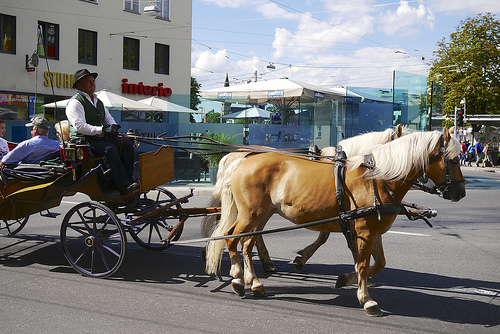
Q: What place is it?
A: It is a parking lot.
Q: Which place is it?
A: It is a parking lot.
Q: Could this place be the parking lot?
A: Yes, it is the parking lot.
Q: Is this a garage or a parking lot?
A: It is a parking lot.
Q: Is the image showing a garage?
A: No, the picture is showing a parking lot.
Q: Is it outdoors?
A: Yes, it is outdoors.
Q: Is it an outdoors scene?
A: Yes, it is outdoors.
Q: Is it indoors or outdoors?
A: It is outdoors.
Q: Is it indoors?
A: No, it is outdoors.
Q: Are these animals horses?
A: Yes, all the animals are horses.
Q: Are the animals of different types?
A: No, all the animals are horses.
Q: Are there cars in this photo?
A: No, there are no cars.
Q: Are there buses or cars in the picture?
A: No, there are no cars or buses.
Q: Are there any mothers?
A: No, there are no mothers.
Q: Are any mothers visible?
A: No, there are no mothers.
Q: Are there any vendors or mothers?
A: No, there are no mothers or vendors.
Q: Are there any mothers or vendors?
A: No, there are no mothers or vendors.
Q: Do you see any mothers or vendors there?
A: No, there are no mothers or vendors.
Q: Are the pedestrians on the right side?
A: Yes, the pedestrians are on the right of the image.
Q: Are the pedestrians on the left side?
A: No, the pedestrians are on the right of the image.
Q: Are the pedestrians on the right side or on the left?
A: The pedestrians are on the right of the image.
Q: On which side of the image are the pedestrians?
A: The pedestrians are on the right of the image.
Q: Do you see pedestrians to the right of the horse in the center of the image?
A: Yes, there are pedestrians to the right of the horse.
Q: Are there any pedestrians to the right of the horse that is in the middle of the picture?
A: Yes, there are pedestrians to the right of the horse.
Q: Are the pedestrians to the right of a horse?
A: Yes, the pedestrians are to the right of a horse.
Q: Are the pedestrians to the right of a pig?
A: No, the pedestrians are to the right of a horse.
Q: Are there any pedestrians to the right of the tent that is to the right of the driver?
A: Yes, there are pedestrians to the right of the tent.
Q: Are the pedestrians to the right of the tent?
A: Yes, the pedestrians are to the right of the tent.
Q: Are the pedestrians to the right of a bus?
A: No, the pedestrians are to the right of the tent.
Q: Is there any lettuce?
A: Yes, there is lettuce.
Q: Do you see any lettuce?
A: Yes, there is lettuce.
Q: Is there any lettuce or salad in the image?
A: Yes, there is lettuce.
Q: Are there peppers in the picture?
A: No, there are no peppers.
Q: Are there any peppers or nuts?
A: No, there are no peppers or nuts.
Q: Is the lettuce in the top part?
A: Yes, the lettuce is in the top of the image.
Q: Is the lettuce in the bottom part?
A: No, the lettuce is in the top of the image.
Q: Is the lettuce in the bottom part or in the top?
A: The lettuce is in the top of the image.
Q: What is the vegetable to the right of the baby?
A: The vegetable is lettuce.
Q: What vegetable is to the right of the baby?
A: The vegetable is lettuce.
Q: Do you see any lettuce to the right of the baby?
A: Yes, there is lettuce to the right of the baby.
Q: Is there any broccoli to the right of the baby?
A: No, there is lettuce to the right of the baby.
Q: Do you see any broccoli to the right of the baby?
A: No, there is lettuce to the right of the baby.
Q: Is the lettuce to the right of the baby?
A: Yes, the lettuce is to the right of the baby.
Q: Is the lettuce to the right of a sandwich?
A: No, the lettuce is to the right of the baby.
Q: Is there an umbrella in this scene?
A: Yes, there is an umbrella.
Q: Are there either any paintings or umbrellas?
A: Yes, there is an umbrella.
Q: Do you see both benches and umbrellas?
A: No, there is an umbrella but no benches.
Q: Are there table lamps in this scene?
A: No, there are no table lamps.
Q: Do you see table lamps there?
A: No, there are no table lamps.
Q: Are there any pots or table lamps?
A: No, there are no table lamps or pots.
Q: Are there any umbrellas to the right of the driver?
A: Yes, there is an umbrella to the right of the driver.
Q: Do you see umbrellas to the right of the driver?
A: Yes, there is an umbrella to the right of the driver.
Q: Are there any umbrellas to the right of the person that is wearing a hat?
A: Yes, there is an umbrella to the right of the driver.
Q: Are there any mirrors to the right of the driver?
A: No, there is an umbrella to the right of the driver.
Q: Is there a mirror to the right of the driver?
A: No, there is an umbrella to the right of the driver.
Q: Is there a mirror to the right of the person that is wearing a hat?
A: No, there is an umbrella to the right of the driver.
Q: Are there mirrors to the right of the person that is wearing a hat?
A: No, there is an umbrella to the right of the driver.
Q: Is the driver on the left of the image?
A: Yes, the driver is on the left of the image.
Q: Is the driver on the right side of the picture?
A: No, the driver is on the left of the image.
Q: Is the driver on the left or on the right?
A: The driver is on the left of the image.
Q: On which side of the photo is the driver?
A: The driver is on the left of the image.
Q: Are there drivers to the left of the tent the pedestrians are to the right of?
A: Yes, there is a driver to the left of the tent.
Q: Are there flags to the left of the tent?
A: No, there is a driver to the left of the tent.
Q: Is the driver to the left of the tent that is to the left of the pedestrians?
A: Yes, the driver is to the left of the tent.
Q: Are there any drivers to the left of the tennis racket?
A: Yes, there is a driver to the left of the tennis racket.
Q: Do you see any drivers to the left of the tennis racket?
A: Yes, there is a driver to the left of the tennis racket.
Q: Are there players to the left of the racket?
A: No, there is a driver to the left of the racket.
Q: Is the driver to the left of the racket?
A: Yes, the driver is to the left of the racket.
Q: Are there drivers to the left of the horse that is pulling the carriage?
A: Yes, there is a driver to the left of the horse.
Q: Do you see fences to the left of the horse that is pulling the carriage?
A: No, there is a driver to the left of the horse.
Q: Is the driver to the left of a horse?
A: Yes, the driver is to the left of a horse.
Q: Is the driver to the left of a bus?
A: No, the driver is to the left of a horse.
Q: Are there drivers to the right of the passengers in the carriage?
A: Yes, there is a driver to the right of the passengers.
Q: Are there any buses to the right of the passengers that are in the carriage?
A: No, there is a driver to the right of the passengers.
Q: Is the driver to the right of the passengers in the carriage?
A: Yes, the driver is to the right of the passengers.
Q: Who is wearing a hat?
A: The driver is wearing a hat.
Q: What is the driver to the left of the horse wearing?
A: The driver is wearing a hat.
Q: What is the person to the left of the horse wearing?
A: The driver is wearing a hat.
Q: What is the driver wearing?
A: The driver is wearing a hat.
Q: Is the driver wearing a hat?
A: Yes, the driver is wearing a hat.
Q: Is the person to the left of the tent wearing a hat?
A: Yes, the driver is wearing a hat.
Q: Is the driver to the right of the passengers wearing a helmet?
A: No, the driver is wearing a hat.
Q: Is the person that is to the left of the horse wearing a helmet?
A: No, the driver is wearing a hat.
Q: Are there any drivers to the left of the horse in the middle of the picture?
A: Yes, there is a driver to the left of the horse.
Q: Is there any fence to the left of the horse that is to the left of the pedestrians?
A: No, there is a driver to the left of the horse.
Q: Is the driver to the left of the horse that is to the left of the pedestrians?
A: Yes, the driver is to the left of the horse.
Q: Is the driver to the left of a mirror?
A: No, the driver is to the left of the horse.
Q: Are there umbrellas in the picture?
A: Yes, there is an umbrella.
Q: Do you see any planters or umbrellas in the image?
A: Yes, there is an umbrella.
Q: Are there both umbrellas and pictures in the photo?
A: No, there is an umbrella but no pictures.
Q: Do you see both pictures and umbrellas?
A: No, there is an umbrella but no pictures.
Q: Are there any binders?
A: No, there are no binders.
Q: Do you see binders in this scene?
A: No, there are no binders.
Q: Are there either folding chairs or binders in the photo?
A: No, there are no binders or folding chairs.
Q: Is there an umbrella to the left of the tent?
A: Yes, there is an umbrella to the left of the tent.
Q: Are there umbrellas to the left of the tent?
A: Yes, there is an umbrella to the left of the tent.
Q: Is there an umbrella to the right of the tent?
A: No, the umbrella is to the left of the tent.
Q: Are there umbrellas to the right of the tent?
A: No, the umbrella is to the left of the tent.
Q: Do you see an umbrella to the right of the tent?
A: No, the umbrella is to the left of the tent.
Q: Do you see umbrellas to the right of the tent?
A: No, the umbrella is to the left of the tent.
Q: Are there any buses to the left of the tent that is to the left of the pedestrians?
A: No, there is an umbrella to the left of the tent.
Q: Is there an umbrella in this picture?
A: Yes, there is an umbrella.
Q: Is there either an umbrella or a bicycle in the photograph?
A: Yes, there is an umbrella.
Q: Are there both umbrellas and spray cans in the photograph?
A: No, there is an umbrella but no spray cans.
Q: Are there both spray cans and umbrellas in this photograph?
A: No, there is an umbrella but no spray cans.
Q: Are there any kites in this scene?
A: No, there are no kites.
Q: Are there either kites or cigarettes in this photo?
A: No, there are no kites or cigarettes.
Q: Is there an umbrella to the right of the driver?
A: Yes, there is an umbrella to the right of the driver.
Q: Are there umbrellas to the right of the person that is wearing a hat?
A: Yes, there is an umbrella to the right of the driver.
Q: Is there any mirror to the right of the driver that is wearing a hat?
A: No, there is an umbrella to the right of the driver.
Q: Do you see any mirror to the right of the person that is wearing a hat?
A: No, there is an umbrella to the right of the driver.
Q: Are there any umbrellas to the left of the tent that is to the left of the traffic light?
A: Yes, there is an umbrella to the left of the tent.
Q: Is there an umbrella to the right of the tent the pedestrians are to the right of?
A: No, the umbrella is to the left of the tent.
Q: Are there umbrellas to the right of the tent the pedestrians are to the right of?
A: No, the umbrella is to the left of the tent.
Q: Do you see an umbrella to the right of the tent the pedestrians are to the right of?
A: No, the umbrella is to the left of the tent.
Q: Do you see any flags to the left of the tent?
A: No, there is an umbrella to the left of the tent.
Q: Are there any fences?
A: No, there are no fences.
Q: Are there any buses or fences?
A: No, there are no fences or buses.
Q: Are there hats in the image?
A: Yes, there is a hat.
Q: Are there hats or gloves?
A: Yes, there is a hat.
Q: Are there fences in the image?
A: No, there are no fences.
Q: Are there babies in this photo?
A: Yes, there is a baby.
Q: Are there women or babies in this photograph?
A: Yes, there is a baby.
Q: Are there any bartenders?
A: No, there are no bartenders.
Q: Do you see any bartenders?
A: No, there are no bartenders.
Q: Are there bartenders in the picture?
A: No, there are no bartenders.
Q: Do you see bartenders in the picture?
A: No, there are no bartenders.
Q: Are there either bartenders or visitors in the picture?
A: No, there are no bartenders or visitors.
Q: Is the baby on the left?
A: Yes, the baby is on the left of the image.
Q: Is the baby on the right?
A: No, the baby is on the left of the image.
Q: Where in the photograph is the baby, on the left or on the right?
A: The baby is on the left of the image.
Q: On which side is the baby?
A: The baby is on the left of the image.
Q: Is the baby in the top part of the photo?
A: Yes, the baby is in the top of the image.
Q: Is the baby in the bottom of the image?
A: No, the baby is in the top of the image.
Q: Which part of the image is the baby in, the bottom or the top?
A: The baby is in the top of the image.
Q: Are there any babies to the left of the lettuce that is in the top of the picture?
A: Yes, there is a baby to the left of the lettuce.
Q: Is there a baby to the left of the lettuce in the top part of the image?
A: Yes, there is a baby to the left of the lettuce.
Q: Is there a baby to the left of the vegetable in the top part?
A: Yes, there is a baby to the left of the lettuce.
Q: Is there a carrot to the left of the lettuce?
A: No, there is a baby to the left of the lettuce.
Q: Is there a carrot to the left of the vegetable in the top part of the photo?
A: No, there is a baby to the left of the lettuce.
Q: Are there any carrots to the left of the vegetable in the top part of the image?
A: No, there is a baby to the left of the lettuce.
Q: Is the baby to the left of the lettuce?
A: Yes, the baby is to the left of the lettuce.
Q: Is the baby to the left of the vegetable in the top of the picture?
A: Yes, the baby is to the left of the lettuce.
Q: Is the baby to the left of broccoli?
A: No, the baby is to the left of the lettuce.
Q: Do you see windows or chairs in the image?
A: Yes, there is a window.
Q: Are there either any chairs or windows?
A: Yes, there is a window.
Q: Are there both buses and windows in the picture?
A: No, there is a window but no buses.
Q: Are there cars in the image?
A: No, there are no cars.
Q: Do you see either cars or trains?
A: No, there are no cars or trains.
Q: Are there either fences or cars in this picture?
A: No, there are no fences or cars.